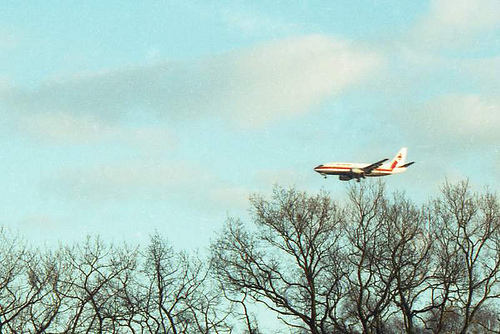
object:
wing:
[363, 157, 389, 172]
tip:
[381, 157, 387, 163]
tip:
[312, 166, 322, 173]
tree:
[133, 227, 201, 332]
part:
[303, 265, 318, 300]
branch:
[259, 232, 297, 256]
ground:
[410, 177, 440, 227]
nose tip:
[311, 167, 318, 171]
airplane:
[313, 145, 417, 181]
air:
[1, 0, 498, 332]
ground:
[421, 127, 443, 158]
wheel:
[355, 177, 363, 182]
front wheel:
[322, 175, 329, 180]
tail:
[389, 146, 415, 172]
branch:
[223, 288, 254, 333]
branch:
[189, 291, 214, 333]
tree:
[421, 173, 499, 332]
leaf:
[283, 203, 288, 213]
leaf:
[298, 221, 310, 234]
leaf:
[282, 194, 296, 201]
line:
[315, 165, 393, 172]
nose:
[313, 165, 323, 172]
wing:
[399, 161, 415, 169]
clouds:
[0, 0, 499, 332]